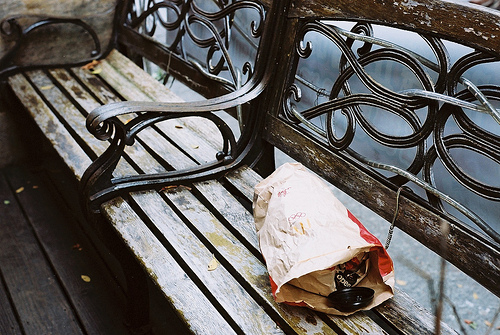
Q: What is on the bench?
A: Paper bag.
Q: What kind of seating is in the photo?
A: Bench.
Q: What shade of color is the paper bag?
A: Brown.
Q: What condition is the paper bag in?
A: Crumpled.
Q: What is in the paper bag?
A: Paper and plastic coffee cup cover.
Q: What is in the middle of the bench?
A: Arm rail.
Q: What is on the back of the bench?
A: Abstract metal design.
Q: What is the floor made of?
A: Wood.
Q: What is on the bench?
A: Bag.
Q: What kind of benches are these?
A: Wooden.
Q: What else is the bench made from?
A: Metal.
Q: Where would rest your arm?
A: Arm rest.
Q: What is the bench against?
A: Stone wall.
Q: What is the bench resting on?
A: Wooden floor.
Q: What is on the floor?
A: Leaves.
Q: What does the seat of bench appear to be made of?
A: Wood.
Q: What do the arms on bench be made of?
A: Metal.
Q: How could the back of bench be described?
A: Ornate.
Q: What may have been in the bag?
A: Fast food.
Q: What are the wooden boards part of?
A: Floor.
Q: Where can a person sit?
A: Benches.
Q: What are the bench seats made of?
A: Wood.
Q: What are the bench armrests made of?
A: Metal.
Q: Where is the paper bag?
A: On the bench.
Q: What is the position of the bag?
A: Laying.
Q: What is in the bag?
A: Garbage.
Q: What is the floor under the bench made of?
A: Wood.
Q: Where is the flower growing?
A: Behind the bench.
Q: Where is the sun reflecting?
A: Armrest.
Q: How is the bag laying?
A: On its side.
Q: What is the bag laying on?
A: A bench.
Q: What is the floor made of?
A: Wood.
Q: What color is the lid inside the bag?
A: Black.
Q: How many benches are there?
A: Two.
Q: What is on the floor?
A: Leaves.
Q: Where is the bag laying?
A: On the right bench.